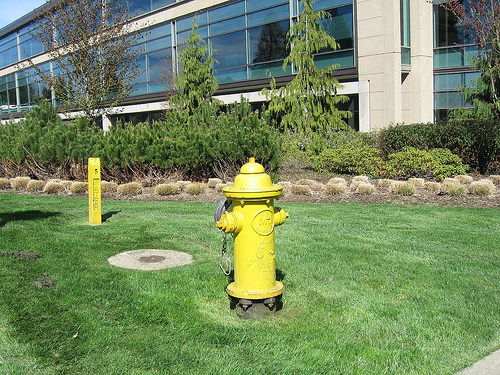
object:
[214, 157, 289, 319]
hydrant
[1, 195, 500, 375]
lawn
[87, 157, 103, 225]
pole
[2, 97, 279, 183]
shrubs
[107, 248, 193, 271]
cement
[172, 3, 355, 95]
windows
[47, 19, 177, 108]
windows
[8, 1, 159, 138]
tree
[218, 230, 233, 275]
chain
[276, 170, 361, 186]
dirt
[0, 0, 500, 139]
building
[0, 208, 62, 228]
shadow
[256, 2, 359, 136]
tree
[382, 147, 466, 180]
bushes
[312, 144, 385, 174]
bushes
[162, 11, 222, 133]
tree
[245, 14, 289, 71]
reflections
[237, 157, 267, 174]
knob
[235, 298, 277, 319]
base